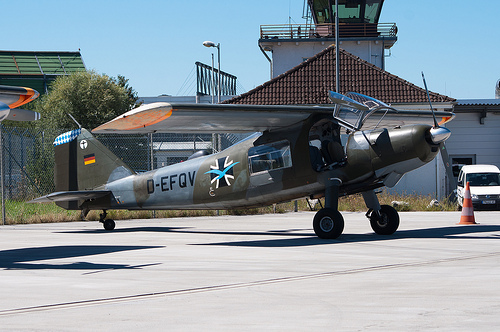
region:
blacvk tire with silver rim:
[280, 209, 346, 267]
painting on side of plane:
[206, 142, 256, 194]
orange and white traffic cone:
[451, 163, 476, 237]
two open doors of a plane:
[257, 83, 424, 215]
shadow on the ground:
[0, 215, 317, 312]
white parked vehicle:
[438, 155, 498, 228]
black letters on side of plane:
[132, 164, 202, 204]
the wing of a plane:
[24, 91, 284, 169]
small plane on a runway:
[17, 95, 449, 280]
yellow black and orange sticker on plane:
[63, 145, 103, 173]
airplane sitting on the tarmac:
[41, 93, 461, 248]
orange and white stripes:
[441, 178, 482, 228]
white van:
[451, 151, 499, 211]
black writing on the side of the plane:
[136, 172, 191, 199]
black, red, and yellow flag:
[77, 149, 102, 171]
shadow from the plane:
[55, 223, 499, 250]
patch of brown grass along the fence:
[10, 196, 435, 223]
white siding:
[443, 114, 496, 156]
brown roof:
[226, 43, 437, 108]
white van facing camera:
[457, 156, 498, 226]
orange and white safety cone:
[454, 177, 498, 243]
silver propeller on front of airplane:
[403, 85, 490, 191]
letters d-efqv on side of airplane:
[132, 162, 244, 228]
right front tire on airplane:
[303, 203, 347, 241]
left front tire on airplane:
[362, 195, 402, 242]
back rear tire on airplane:
[88, 206, 125, 243]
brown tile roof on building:
[288, 61, 363, 106]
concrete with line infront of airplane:
[321, 239, 454, 330]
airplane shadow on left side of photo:
[26, 223, 150, 298]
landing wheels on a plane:
[250, 196, 427, 261]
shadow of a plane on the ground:
[4, 222, 173, 294]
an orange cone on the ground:
[441, 170, 498, 234]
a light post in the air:
[197, 32, 233, 97]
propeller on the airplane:
[404, 56, 491, 223]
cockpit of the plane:
[222, 85, 375, 210]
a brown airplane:
[25, 55, 453, 280]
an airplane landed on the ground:
[37, 38, 479, 258]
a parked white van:
[442, 147, 498, 228]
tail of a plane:
[20, 94, 185, 249]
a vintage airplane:
[58, 79, 466, 239]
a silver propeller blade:
[417, 70, 463, 197]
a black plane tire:
[311, 204, 346, 242]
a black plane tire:
[370, 205, 398, 233]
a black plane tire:
[100, 216, 110, 228]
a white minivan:
[450, 156, 498, 209]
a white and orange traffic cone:
[455, 177, 477, 227]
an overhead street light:
[198, 35, 224, 107]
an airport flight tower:
[255, 1, 397, 76]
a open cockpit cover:
[322, 85, 387, 134]